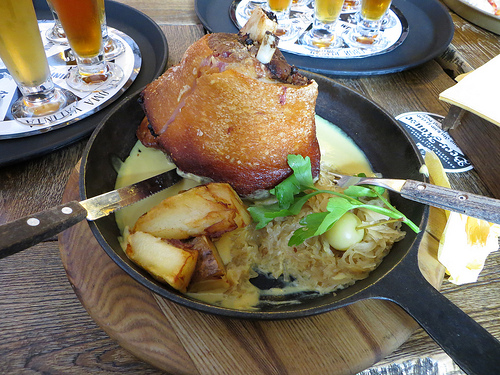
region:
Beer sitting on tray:
[1, 1, 170, 167]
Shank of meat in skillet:
[136, 5, 324, 180]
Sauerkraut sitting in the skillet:
[261, 181, 405, 294]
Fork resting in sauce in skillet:
[318, 170, 498, 226]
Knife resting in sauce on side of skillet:
[1, 165, 184, 256]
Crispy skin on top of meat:
[144, 33, 320, 188]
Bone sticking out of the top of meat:
[240, 5, 278, 42]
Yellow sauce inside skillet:
[314, 113, 374, 177]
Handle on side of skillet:
[376, 252, 499, 374]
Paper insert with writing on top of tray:
[1, 15, 143, 141]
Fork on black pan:
[317, 167, 498, 224]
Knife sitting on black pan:
[0, 165, 181, 260]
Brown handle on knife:
[0, 199, 87, 268]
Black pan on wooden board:
[75, 60, 499, 373]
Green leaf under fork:
[332, 168, 424, 238]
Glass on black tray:
[0, 0, 78, 123]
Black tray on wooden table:
[0, 0, 167, 170]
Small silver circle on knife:
[60, 205, 72, 215]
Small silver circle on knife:
[25, 216, 40, 226]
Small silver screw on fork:
[455, 191, 468, 201]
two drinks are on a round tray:
[3, 1, 158, 149]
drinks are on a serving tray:
[196, 0, 453, 82]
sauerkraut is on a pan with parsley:
[262, 170, 406, 295]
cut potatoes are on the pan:
[125, 183, 254, 305]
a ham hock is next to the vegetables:
[151, 10, 325, 192]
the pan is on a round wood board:
[60, 93, 455, 373]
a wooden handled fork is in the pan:
[313, 158, 499, 222]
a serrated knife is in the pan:
[9, 165, 183, 239]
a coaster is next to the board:
[392, 103, 471, 172]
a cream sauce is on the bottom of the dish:
[121, 120, 379, 282]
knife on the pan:
[2, 145, 190, 302]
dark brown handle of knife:
[3, 204, 81, 254]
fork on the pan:
[328, 166, 497, 225]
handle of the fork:
[403, 176, 498, 233]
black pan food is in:
[81, 64, 488, 364]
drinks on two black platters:
[3, 0, 465, 165]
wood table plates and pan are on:
[9, 7, 498, 371]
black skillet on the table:
[75, 67, 493, 352]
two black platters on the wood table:
[1, 6, 465, 179]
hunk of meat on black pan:
[135, 7, 325, 185]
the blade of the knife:
[87, 162, 181, 224]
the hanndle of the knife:
[1, 187, 86, 259]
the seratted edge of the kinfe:
[104, 181, 194, 231]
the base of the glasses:
[1, 55, 126, 120]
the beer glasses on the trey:
[1, 2, 126, 99]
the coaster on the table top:
[397, 99, 473, 179]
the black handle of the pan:
[383, 258, 496, 373]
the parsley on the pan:
[261, 150, 417, 238]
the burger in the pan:
[140, 34, 312, 190]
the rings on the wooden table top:
[5, 328, 135, 372]